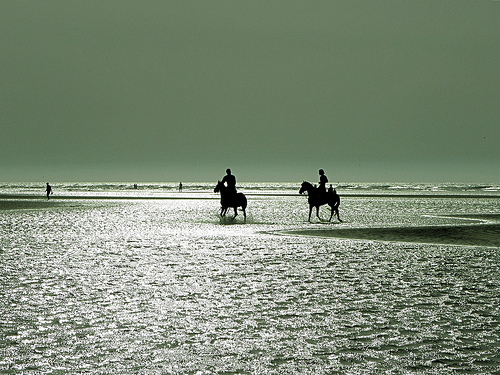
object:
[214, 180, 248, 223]
horse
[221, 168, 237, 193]
rider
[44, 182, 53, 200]
person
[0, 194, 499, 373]
beach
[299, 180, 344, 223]
horse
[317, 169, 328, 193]
rider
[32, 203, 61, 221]
water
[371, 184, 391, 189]
waves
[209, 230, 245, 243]
runing in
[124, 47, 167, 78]
sky